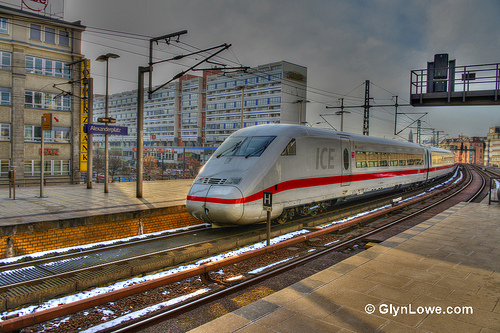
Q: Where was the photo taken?
A: It was taken at the sidewalk.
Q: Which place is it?
A: It is a sidewalk.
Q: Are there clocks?
A: No, there are no clocks.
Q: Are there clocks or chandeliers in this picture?
A: No, there are no clocks or chandeliers.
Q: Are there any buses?
A: No, there are no buses.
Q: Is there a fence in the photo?
A: No, there are no fences.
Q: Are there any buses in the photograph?
A: No, there are no buses.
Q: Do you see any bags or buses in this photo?
A: No, there are no buses or bags.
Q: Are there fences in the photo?
A: No, there are no fences.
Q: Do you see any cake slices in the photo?
A: No, there are no cake slices.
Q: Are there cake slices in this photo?
A: No, there are no cake slices.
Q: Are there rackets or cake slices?
A: No, there are no cake slices or rackets.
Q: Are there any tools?
A: No, there are no tools.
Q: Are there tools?
A: No, there are no tools.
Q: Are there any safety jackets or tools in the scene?
A: No, there are no tools or safety jackets.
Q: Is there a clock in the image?
A: No, there are no clocks.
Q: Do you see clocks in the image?
A: No, there are no clocks.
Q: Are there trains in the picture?
A: Yes, there is a train.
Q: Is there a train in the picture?
A: Yes, there is a train.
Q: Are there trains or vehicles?
A: Yes, there is a train.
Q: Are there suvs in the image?
A: No, there are no suvs.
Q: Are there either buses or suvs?
A: No, there are no suvs or buses.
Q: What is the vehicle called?
A: The vehicle is a train.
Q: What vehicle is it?
A: The vehicle is a train.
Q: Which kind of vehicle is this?
A: This is a train.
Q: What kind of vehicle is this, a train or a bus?
A: This is a train.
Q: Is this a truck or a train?
A: This is a train.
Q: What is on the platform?
A: The train is on the platform.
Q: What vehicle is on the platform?
A: The vehicle is a train.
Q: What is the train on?
A: The train is on the platform.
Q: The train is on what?
A: The train is on the platform.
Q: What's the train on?
A: The train is on the platform.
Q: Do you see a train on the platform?
A: Yes, there is a train on the platform.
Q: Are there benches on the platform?
A: No, there is a train on the platform.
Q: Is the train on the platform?
A: Yes, the train is on the platform.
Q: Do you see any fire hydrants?
A: No, there are no fire hydrants.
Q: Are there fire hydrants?
A: No, there are no fire hydrants.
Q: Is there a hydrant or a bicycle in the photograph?
A: No, there are no fire hydrants or bicycles.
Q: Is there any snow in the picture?
A: Yes, there is snow.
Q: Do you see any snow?
A: Yes, there is snow.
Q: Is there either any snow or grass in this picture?
A: Yes, there is snow.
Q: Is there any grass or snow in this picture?
A: Yes, there is snow.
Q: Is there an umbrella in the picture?
A: No, there are no umbrellas.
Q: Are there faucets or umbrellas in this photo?
A: No, there are no umbrellas or faucets.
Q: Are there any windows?
A: Yes, there are windows.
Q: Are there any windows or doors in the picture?
A: Yes, there are windows.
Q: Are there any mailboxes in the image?
A: No, there are no mailboxes.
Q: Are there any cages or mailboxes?
A: No, there are no mailboxes or cages.